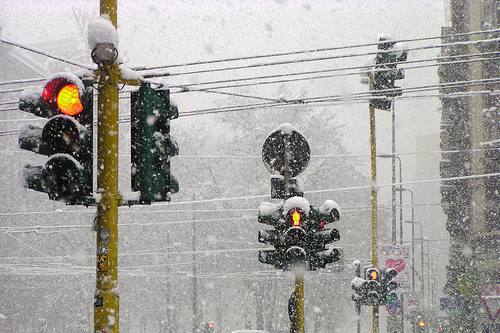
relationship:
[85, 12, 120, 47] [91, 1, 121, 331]
snow on pole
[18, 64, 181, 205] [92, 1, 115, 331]
traffic light on pole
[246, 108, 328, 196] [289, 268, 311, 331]
sign on pole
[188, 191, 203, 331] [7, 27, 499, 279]
wooden pole near lines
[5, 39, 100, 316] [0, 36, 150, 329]
side of building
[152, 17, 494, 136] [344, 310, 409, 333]
wire hanging above road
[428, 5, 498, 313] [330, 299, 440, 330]
building by road